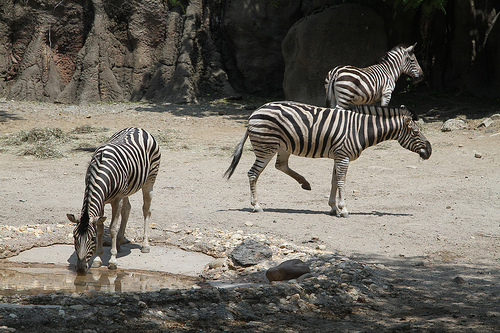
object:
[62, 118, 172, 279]
zebra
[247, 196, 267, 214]
hooves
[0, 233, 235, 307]
wateing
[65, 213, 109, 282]
drink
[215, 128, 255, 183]
tail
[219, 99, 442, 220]
zebras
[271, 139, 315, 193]
left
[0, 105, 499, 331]
ground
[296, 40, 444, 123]
moving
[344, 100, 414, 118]
mane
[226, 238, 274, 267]
stones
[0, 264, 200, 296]
water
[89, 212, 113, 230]
ears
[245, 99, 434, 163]
side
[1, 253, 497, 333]
tree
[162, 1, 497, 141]
habitat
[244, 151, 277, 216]
legs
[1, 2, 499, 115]
rock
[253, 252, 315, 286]
rocks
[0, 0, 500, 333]
area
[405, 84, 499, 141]
patches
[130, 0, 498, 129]
shadow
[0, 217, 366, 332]
rim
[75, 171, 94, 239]
black